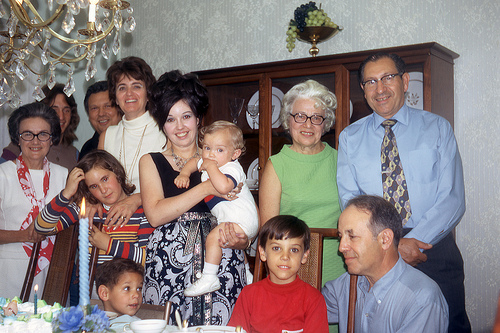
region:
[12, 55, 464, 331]
group of people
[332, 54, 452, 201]
man is wearing a tie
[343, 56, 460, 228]
man is wearing eye glasses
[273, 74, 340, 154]
woman has on black framed glasses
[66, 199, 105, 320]
spiral shaped candle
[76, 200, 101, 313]
candle is lit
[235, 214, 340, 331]
boy is wearing a red shirt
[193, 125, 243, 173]
bay has hand in mouth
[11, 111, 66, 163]
woman is wearing black framed glasses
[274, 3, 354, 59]
gold bowl of plastic grapes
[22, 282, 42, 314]
lit candle on the cake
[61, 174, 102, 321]
lit candle on the table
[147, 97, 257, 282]
baby in his mother's arms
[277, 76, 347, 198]
woman with grey hair and glasses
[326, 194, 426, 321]
man kneeling down looking at boy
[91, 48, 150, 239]
woman with her hand on girl's shoulder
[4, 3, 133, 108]
chandelier hanging from the ceiling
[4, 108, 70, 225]
woman wearing glasses and red and white scarf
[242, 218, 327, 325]
small boy in red shirt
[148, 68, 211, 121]
The hair of the woman is black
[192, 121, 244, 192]
The baby is looking forward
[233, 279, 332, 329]
The boy has on a red shirt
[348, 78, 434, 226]
The man is wearing a tie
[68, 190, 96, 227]
The light on the candle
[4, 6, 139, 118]
The chandelier hanging from the wall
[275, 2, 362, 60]
A decorative bowl of grapes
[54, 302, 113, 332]
The flowers on the table are blue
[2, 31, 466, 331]
The family is standing together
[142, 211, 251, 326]
The woman has a white and black skirt on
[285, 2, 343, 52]
gold platter of grapes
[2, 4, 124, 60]
gold chandelier with crystals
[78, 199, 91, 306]
tall blue candle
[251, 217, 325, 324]
boy wearing a red shirt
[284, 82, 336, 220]
woman wearing glasses and a green dress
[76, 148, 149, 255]
girl wearing a striped shirt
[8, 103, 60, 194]
woman in a white dress wearing glasses and a red and white scarf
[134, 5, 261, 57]
white patterned wallpaper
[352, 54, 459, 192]
man wearing glasses and a necktie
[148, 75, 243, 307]
woman wearing a black and white dress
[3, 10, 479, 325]
family posing for photograph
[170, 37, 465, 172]
large wood and glass china cabinet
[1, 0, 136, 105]
chandelier with hanging crystals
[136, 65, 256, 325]
woman holding toddler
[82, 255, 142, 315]
boy looking sideways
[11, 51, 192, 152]
people smiling in dining room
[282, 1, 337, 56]
grapes hanging from raised bowl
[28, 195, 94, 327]
tall and short lit candles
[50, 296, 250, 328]
blue roses and dinnerware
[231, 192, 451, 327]
man turned toward boy